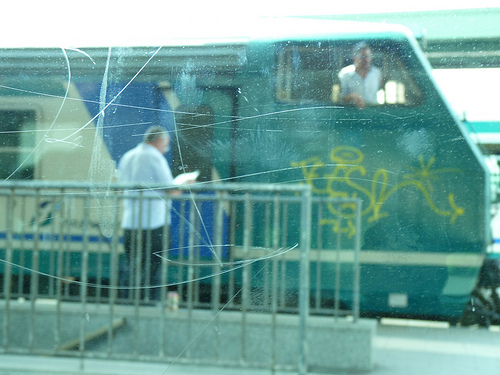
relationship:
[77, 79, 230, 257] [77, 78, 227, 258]
blue  siding blue siding blue  siding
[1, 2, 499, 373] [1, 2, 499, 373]
photo  not clear photo not clear photo  not clear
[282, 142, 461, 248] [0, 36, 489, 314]
graffitti on train on train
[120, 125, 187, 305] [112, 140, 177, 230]
man in shirt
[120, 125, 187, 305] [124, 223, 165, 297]
man wearing black pants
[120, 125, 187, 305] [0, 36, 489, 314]
man waiting for train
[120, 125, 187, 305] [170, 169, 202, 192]
man holding newspaper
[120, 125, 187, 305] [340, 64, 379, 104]
man wearing white shirt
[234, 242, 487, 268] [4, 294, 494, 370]
white strip drawn on path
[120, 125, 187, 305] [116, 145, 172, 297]
man wearing clothes